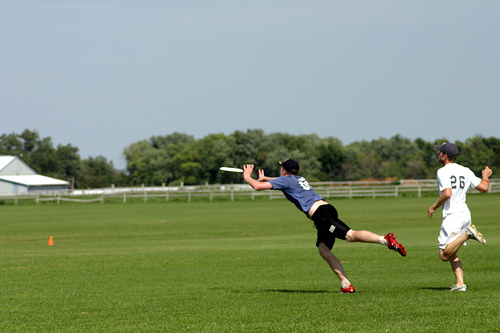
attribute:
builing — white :
[3, 144, 91, 229]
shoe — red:
[467, 224, 487, 243]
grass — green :
[1, 190, 498, 331]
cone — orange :
[45, 222, 60, 252]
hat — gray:
[431, 141, 458, 158]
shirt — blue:
[269, 176, 325, 213]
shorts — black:
[311, 202, 352, 248]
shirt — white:
[422, 163, 489, 227]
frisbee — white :
[216, 160, 243, 176]